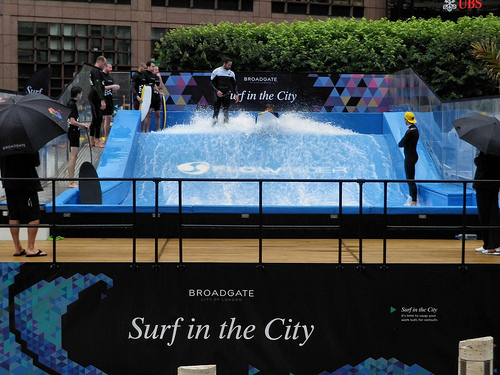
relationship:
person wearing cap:
[394, 109, 420, 206] [404, 110, 417, 124]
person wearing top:
[394, 109, 420, 206] [397, 125, 419, 153]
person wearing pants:
[394, 109, 420, 206] [403, 153, 418, 201]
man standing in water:
[207, 55, 240, 124] [113, 107, 409, 204]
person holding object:
[134, 62, 155, 132] [139, 85, 156, 121]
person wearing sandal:
[0, 91, 74, 254] [25, 249, 48, 257]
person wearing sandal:
[0, 91, 74, 254] [12, 246, 27, 257]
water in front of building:
[113, 107, 409, 204] [2, 0, 388, 99]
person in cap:
[394, 109, 420, 206] [404, 110, 417, 124]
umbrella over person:
[0, 90, 77, 156] [0, 91, 74, 254]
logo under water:
[175, 159, 349, 179] [113, 107, 409, 204]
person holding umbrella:
[0, 91, 74, 254] [0, 90, 77, 156]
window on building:
[15, 21, 35, 37] [2, 0, 388, 99]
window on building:
[115, 24, 133, 38] [2, 0, 388, 99]